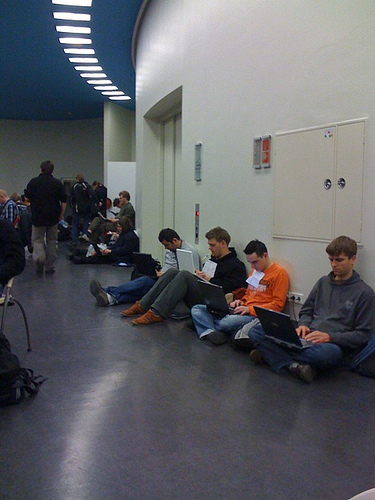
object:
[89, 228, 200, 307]
man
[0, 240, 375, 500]
floor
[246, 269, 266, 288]
paper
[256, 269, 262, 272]
chin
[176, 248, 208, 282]
laptop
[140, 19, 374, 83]
wall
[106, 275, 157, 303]
jeans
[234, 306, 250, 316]
hand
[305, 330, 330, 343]
hand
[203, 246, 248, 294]
hoodie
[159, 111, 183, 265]
doors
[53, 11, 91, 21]
light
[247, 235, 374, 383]
male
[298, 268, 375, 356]
hoodie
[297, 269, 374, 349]
shirt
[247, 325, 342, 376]
jeans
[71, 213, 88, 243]
jeans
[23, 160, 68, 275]
man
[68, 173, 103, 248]
man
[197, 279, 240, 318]
laptop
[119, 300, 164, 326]
shoes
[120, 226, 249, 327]
man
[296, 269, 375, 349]
grey jacket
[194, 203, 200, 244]
buttons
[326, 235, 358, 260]
hair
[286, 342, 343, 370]
leg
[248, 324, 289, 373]
leg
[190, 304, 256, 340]
jeans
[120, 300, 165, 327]
feet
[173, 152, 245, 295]
wall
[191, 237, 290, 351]
man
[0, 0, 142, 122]
ceiling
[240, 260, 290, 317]
shirt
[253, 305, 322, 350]
laptop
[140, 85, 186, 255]
elevator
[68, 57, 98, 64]
light